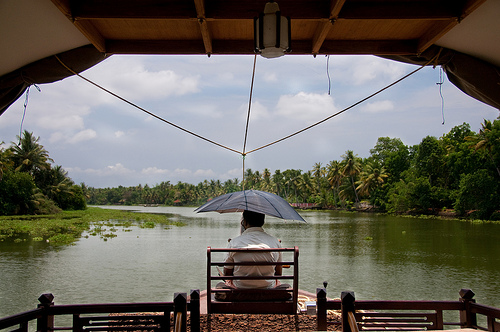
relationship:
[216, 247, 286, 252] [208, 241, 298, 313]
part of chair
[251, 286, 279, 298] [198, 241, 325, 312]
part of chair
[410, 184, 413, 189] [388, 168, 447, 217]
leaf on bush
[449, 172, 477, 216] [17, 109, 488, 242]
tree in woods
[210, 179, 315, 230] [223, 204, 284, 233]
umbrella over head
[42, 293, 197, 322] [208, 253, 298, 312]
railings around seat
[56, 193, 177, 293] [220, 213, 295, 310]
water in front of man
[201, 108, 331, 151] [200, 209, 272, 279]
ropes above man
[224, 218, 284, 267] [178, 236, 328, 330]
man in chair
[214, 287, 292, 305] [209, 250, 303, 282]
cushion in chair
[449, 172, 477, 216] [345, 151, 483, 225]
tree in woods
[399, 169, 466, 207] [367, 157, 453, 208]
tree in woods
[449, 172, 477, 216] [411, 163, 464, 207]
tree in woods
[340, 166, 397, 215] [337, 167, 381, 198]
tree in woods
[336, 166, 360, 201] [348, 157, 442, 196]
tree in woods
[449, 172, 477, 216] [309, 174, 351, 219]
tree in woods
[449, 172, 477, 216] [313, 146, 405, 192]
tree in woods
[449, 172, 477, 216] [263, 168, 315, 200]
tree in woods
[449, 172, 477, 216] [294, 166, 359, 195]
tree in woods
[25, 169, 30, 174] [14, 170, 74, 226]
leaf on plant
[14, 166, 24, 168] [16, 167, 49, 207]
leaf on plant